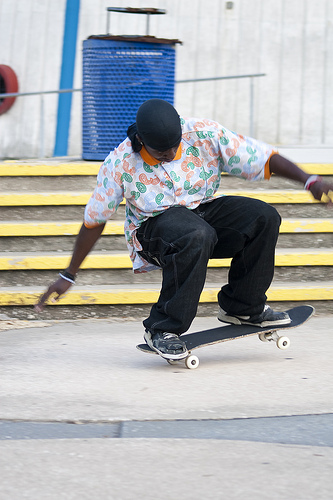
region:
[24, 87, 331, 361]
This is a person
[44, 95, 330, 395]
This is a person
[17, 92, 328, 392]
This is a person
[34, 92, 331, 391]
This is a person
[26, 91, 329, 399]
This is a person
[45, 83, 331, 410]
This is a person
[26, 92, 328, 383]
This is a person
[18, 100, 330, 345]
This is a person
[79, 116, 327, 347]
skater is on a board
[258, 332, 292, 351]
white wheels in the air on the skateboard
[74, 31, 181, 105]
blue trashcan behind the skater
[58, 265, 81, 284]
skater is wearing bracelets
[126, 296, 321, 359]
skater is riding a skateboard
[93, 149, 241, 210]
skater is wearing a print shirt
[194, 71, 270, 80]
railing behind the skater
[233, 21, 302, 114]
metal building behind the skater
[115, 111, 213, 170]
the head of a man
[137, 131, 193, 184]
the face of a man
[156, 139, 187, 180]
the nose of a man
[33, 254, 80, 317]
the hand of a man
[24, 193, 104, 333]
the arm of a man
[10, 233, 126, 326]
the fingers of a man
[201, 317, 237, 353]
this is a skateboard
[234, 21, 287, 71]
this is a wall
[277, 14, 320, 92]
the wall is white in color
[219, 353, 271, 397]
this is the ground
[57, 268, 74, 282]
this is a wrist band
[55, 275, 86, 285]
the band is white in color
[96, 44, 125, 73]
this is a tin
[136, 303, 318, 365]
a black skateboard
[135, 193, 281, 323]
a man's black jean pants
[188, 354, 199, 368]
a small white skateboard wheel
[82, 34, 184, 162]
a blue trash can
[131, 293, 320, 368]
black skateboard on sidewalk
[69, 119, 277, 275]
floral white shirt on black boy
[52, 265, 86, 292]
black and white bracelets on boy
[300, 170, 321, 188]
orange and white bracelets on boy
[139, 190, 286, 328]
black jeans on boy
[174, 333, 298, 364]
white wheels on black skateboard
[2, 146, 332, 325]
yellow and gray concrete steps behind boy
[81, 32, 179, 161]
blue metal trash can behind boy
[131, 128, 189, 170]
orange collar on white shirt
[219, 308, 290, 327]
dark shoe on skateboard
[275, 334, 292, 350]
white wheel on skateboard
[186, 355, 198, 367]
white wheel on skateboard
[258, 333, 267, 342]
white wheel on skateboard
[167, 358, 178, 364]
white wheel on skateboard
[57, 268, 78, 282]
bracelet around guys wrist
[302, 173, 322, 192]
bracelet around guys wrist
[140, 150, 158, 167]
orange collar on shirt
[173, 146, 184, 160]
orange collar on shirt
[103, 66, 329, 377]
the man is skating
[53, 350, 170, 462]
the pavement is gray and blue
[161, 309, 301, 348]
the skateboard is black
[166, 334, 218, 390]
the wheels are white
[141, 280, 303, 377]
the man is balancing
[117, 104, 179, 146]
the man has a du rag on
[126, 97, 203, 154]
the du rag is black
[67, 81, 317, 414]
the man is skating